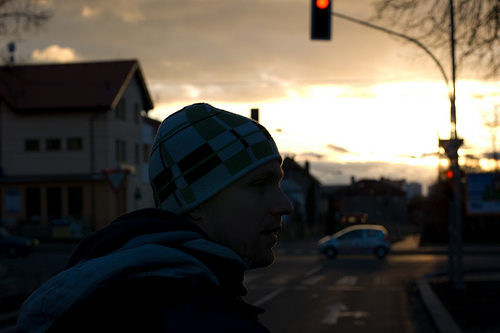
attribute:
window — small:
[65, 133, 87, 151]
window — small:
[38, 133, 64, 153]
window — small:
[74, 186, 90, 233]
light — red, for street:
[308, 1, 334, 41]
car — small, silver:
[313, 222, 390, 257]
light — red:
[310, 3, 334, 44]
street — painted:
[251, 225, 455, 331]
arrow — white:
[321, 293, 362, 331]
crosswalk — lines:
[253, 268, 414, 295]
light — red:
[307, 0, 335, 35]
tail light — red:
[384, 238, 393, 249]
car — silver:
[321, 220, 391, 260]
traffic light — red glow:
[311, 1, 331, 41]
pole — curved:
[340, 7, 449, 77]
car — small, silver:
[316, 224, 392, 262]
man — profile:
[14, 102, 302, 331]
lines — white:
[226, 265, 415, 295]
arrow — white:
[318, 293, 372, 328]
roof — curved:
[5, 59, 157, 113]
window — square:
[27, 137, 43, 156]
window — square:
[48, 140, 67, 155]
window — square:
[66, 140, 81, 157]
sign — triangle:
[103, 162, 138, 202]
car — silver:
[302, 205, 405, 263]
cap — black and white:
[139, 90, 316, 202]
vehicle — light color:
[306, 226, 469, 291]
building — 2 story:
[22, 47, 153, 239]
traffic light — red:
[309, 0, 336, 20]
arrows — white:
[315, 288, 365, 320]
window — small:
[20, 127, 60, 166]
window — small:
[23, 192, 44, 225]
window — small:
[135, 102, 142, 125]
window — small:
[132, 140, 141, 165]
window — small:
[109, 132, 127, 167]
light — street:
[307, 3, 336, 42]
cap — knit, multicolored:
[144, 103, 282, 218]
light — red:
[314, 1, 331, 13]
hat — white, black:
[147, 101, 278, 223]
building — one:
[10, 50, 172, 218]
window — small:
[111, 90, 135, 126]